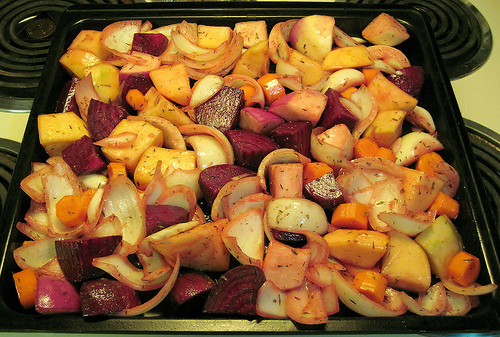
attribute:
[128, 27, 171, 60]
beet — cooking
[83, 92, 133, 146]
beet — cooking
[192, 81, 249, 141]
beet — cooking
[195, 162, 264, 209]
beet — cooking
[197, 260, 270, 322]
beet — cooking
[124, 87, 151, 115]
carrot — cooking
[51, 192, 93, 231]
carrot — cooking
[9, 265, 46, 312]
carrot — cooking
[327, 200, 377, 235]
carrot — cooking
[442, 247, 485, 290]
carrot — cooking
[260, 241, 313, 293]
onion — steaming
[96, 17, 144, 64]
onion — steaming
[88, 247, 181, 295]
onion — steaming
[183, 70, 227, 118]
onion — steaming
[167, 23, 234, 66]
onion — steaming